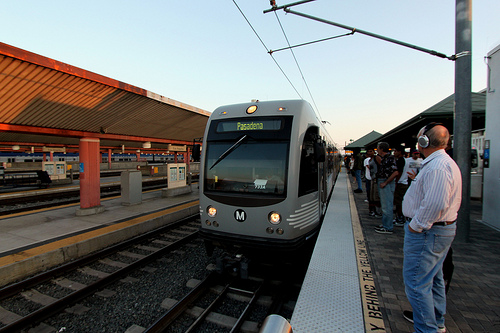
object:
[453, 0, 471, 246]
pole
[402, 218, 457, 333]
jeans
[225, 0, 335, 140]
wires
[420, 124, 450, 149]
hair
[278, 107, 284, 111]
light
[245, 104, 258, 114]
light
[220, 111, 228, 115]
light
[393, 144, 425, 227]
people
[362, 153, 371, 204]
person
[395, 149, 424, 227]
person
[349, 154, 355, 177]
person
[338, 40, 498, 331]
station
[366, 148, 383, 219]
people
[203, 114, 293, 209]
windshield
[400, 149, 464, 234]
shirt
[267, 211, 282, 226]
headlight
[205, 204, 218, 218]
headlight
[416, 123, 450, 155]
head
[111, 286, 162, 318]
gravel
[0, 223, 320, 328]
railroad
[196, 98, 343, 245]
train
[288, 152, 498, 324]
platform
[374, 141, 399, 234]
man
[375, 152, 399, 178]
black shirt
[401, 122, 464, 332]
man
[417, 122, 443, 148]
headphones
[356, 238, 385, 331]
word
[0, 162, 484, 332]
ground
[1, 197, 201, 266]
lines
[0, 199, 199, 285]
border